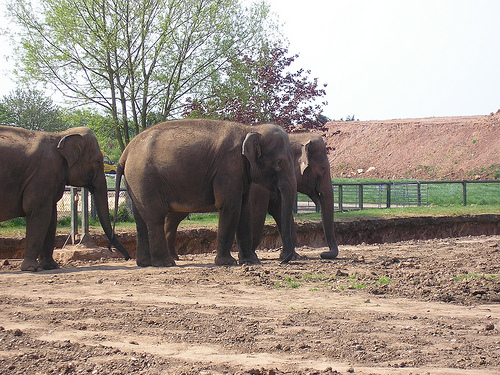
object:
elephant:
[107, 118, 299, 269]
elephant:
[162, 135, 338, 262]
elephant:
[0, 125, 131, 272]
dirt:
[0, 233, 500, 374]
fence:
[60, 181, 499, 211]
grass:
[0, 176, 499, 238]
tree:
[179, 40, 340, 174]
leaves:
[304, 108, 312, 115]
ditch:
[1, 213, 500, 259]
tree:
[54, 106, 134, 171]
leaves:
[91, 118, 110, 131]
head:
[294, 132, 335, 213]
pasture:
[1, 177, 499, 236]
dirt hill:
[281, 114, 497, 175]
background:
[1, 0, 500, 181]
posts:
[70, 184, 79, 246]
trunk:
[317, 186, 339, 260]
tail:
[108, 160, 123, 253]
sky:
[0, 0, 499, 122]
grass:
[269, 272, 496, 293]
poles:
[460, 181, 467, 206]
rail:
[63, 178, 498, 193]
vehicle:
[99, 149, 118, 174]